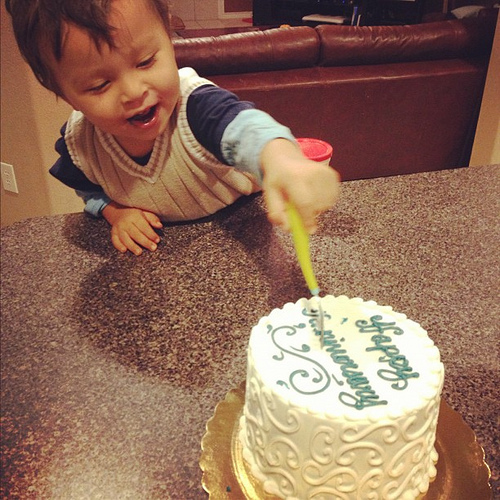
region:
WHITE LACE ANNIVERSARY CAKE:
[231, 301, 451, 497]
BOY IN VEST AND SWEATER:
[0, 1, 355, 258]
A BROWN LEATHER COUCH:
[153, 17, 473, 167]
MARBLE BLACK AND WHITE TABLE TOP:
[2, 166, 493, 496]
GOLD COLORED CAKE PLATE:
[193, 380, 495, 490]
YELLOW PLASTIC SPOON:
[272, 195, 334, 350]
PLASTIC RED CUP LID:
[276, 120, 341, 168]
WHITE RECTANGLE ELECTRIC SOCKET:
[0, 155, 25, 195]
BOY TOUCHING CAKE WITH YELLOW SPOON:
[30, 0, 476, 496]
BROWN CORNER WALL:
[1, 57, 85, 212]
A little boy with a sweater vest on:
[1, 6, 371, 256]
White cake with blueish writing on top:
[217, 293, 467, 498]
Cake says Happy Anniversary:
[293, 291, 450, 424]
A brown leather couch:
[176, 17, 496, 179]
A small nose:
[113, 71, 153, 107]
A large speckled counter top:
[3, 196, 498, 481]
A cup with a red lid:
[280, 118, 340, 187]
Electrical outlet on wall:
[0, 146, 16, 203]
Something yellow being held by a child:
[263, 184, 345, 344]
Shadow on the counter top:
[56, 213, 256, 386]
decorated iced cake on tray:
[242, 289, 444, 498]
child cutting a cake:
[4, 0, 341, 257]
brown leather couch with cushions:
[171, 16, 498, 183]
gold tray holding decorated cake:
[199, 376, 492, 498]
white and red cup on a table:
[281, 134, 332, 236]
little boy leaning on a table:
[9, 0, 343, 253]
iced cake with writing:
[237, 296, 445, 498]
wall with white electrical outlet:
[1, 0, 87, 219]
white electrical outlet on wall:
[0, 161, 20, 195]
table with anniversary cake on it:
[2, 159, 498, 496]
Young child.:
[2, 0, 209, 141]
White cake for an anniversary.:
[200, 295, 465, 497]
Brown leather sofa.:
[327, 15, 489, 170]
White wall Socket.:
[0, 160, 20, 195]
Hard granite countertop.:
[5, 255, 195, 490]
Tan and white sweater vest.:
[55, 125, 275, 230]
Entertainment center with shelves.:
[240, 0, 460, 30]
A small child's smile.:
[110, 100, 175, 130]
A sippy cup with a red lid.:
[290, 130, 340, 165]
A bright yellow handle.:
[275, 200, 335, 296]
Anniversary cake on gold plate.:
[198, 291, 493, 499]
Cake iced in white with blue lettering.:
[228, 294, 445, 499]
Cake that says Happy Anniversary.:
[238, 295, 446, 499]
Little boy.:
[7, 2, 342, 254]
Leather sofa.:
[171, 20, 486, 181]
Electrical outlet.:
[0, 158, 19, 195]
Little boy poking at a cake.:
[5, 0, 445, 499]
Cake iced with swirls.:
[233, 291, 446, 498]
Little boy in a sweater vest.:
[2, 0, 344, 257]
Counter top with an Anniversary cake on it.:
[0, 166, 499, 498]